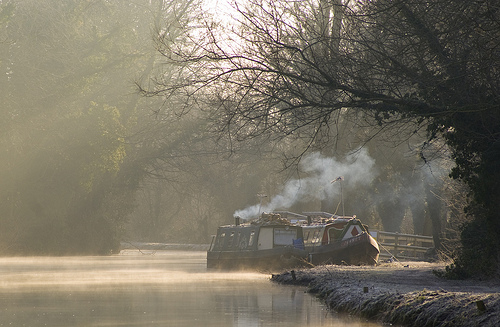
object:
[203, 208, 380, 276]
old boat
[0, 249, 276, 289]
sun reflection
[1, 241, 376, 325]
water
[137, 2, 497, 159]
branches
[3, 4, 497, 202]
sky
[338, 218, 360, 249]
square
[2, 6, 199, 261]
trees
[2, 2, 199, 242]
leaves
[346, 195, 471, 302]
fence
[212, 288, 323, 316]
shadow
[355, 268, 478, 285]
shadow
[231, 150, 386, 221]
smoke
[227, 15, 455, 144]
tree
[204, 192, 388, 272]
boat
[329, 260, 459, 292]
ground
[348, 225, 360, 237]
diamond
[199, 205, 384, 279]
boats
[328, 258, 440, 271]
light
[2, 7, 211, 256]
tree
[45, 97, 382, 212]
air